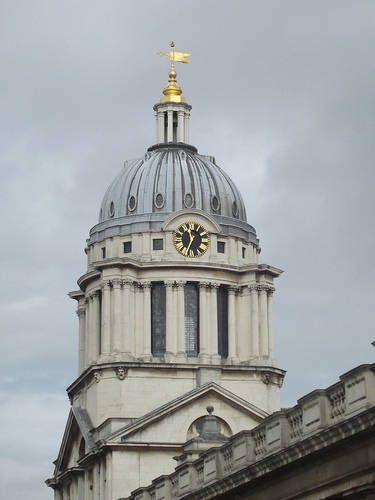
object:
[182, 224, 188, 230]
roman numeral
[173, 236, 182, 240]
roman numeral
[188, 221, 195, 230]
numeral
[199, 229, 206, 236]
numeral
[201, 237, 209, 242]
numeral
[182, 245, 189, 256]
numeral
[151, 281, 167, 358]
windows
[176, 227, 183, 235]
roman letters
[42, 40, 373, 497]
building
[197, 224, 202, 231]
roman numeral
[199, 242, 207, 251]
roman numeral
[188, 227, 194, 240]
hand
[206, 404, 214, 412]
ball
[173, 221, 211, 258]
clock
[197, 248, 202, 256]
roman numerals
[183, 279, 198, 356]
window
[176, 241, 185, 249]
numbers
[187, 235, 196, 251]
hand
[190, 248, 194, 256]
numbers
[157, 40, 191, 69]
flag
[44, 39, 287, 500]
tower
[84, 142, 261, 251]
dome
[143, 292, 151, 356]
column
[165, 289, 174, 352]
column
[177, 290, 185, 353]
column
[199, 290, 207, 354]
column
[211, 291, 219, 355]
column